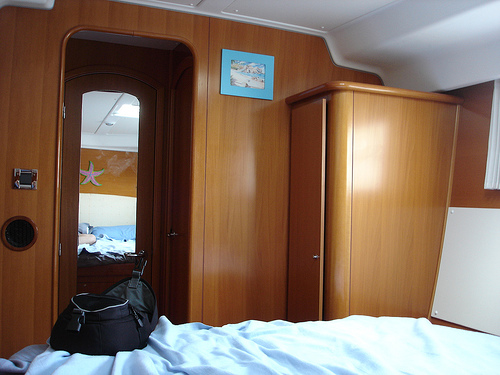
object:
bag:
[49, 257, 155, 357]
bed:
[2, 320, 499, 374]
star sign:
[79, 160, 106, 187]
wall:
[78, 148, 138, 227]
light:
[234, 137, 254, 197]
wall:
[0, 0, 376, 327]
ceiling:
[81, 89, 135, 137]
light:
[116, 103, 140, 120]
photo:
[229, 58, 264, 90]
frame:
[220, 48, 275, 101]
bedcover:
[24, 314, 499, 374]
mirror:
[78, 88, 140, 295]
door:
[58, 71, 157, 295]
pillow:
[91, 225, 137, 240]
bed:
[77, 232, 137, 260]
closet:
[285, 80, 464, 322]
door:
[287, 98, 327, 322]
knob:
[312, 254, 319, 259]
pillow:
[77, 222, 94, 235]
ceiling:
[1, 1, 500, 49]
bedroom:
[1, 0, 499, 374]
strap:
[64, 306, 86, 332]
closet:
[196, 16, 315, 316]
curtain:
[483, 78, 499, 190]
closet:
[57, 37, 170, 298]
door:
[169, 65, 193, 324]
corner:
[59, 37, 194, 325]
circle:
[0, 215, 39, 251]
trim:
[1, 214, 40, 252]